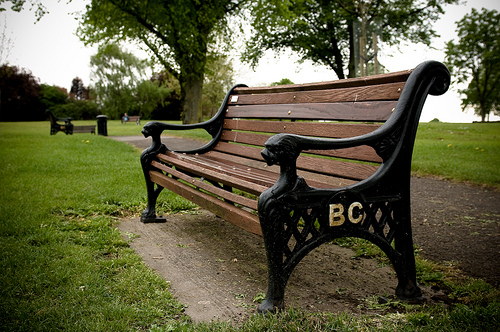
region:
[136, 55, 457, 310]
an outdoor park bench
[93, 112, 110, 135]
a metal trash can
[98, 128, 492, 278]
a paved walk and bike path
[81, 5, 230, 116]
a large green tree in distance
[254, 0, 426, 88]
a large green tree in distance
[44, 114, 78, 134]
a park bench in distance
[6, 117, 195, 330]
a patch of green grass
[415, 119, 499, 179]
a patch of green grass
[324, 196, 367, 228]
the letters B and C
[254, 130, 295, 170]
metal arm rest with animal face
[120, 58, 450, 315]
black and brown bench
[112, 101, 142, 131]
person sitting on bench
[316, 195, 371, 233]
letters on side of bench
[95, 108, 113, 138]
black trash can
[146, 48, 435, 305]
bench in the park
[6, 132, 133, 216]
large green grass field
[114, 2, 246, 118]
large tree in background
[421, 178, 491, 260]
dark gravel trail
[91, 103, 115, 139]
trash can next to bench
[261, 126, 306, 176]
black arm handles on bench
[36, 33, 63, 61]
this is the sky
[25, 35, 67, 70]
the sky is full of clouds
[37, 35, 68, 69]
the clouds are white in color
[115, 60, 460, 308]
this is a bench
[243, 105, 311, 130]
the bench is made of wood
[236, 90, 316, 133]
the wood is brown in color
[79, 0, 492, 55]
these are several trees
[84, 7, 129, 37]
the leaves are green in color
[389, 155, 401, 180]
the handle is black in color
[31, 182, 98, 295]
the grass is green in color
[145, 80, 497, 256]
bench has iron sides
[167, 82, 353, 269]
bench has wood slats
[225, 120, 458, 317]
iron on the bench is black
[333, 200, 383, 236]
BC is written on side of bench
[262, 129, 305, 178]
animal head on the bench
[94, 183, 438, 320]
bench on a cement pad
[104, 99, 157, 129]
person sitting on a bench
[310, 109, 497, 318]
sidewalk behind the bench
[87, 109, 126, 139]
trash can along sidewalk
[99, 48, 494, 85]
trees in the middle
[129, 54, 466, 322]
a wooden bench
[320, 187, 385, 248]
letters BC on the bench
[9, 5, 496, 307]
a scene of a park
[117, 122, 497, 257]
a gray trail behind the bench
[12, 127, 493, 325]
a green field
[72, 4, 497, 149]
a row of green trees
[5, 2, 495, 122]
a sky that is white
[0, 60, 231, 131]
some trees in the background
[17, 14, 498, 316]
a scene outside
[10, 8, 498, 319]
a scene happening during the day